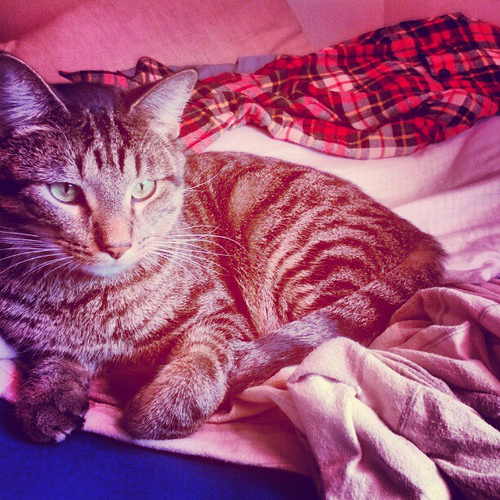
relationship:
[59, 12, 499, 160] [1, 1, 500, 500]
blanket on couch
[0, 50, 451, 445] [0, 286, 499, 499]
cat on blanket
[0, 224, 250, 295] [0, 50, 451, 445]
whiskers of cat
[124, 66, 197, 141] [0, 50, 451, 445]
ear of cat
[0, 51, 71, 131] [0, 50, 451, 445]
ear of cat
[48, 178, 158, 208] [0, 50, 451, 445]
eyes of cat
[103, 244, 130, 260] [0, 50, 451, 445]
nose of cat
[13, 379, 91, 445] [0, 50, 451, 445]
paw of cat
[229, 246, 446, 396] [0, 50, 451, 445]
tail of cat